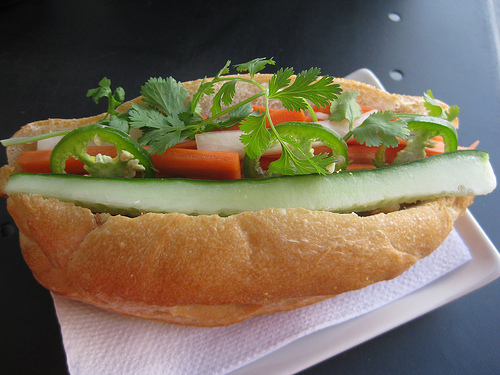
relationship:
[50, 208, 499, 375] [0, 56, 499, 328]
napkin under sandwhich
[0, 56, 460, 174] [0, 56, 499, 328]
cilantro on sandwhich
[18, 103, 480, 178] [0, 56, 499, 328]
carrots on sandwhich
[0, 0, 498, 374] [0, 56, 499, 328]
table under sandwhich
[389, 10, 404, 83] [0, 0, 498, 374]
holes on table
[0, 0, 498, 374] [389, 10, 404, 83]
table has holes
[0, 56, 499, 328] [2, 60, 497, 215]
sandwhich of vegetables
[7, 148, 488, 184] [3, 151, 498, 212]
peel on pickle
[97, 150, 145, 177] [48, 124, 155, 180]
seeds in jalepeno pepper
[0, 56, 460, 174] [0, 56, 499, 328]
cilantro on top of sandwhich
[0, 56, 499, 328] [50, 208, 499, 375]
sandwhich on napkin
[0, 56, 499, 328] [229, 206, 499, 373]
sandwhich on plate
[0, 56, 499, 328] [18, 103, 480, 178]
sandwhich has carrots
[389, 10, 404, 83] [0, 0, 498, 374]
holes in table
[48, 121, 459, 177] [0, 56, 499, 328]
jalepeno peppers on sandwhich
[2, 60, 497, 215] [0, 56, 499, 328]
vegetables on sandwhich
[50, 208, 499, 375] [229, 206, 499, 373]
napkin on plate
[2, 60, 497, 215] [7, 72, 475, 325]
vegetables on bread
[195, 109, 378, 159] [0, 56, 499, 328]
onion on sandwhich